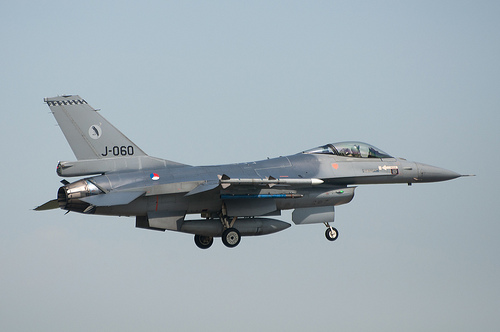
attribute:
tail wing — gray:
[43, 94, 146, 159]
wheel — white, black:
[222, 226, 240, 247]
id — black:
[100, 143, 135, 158]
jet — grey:
[34, 82, 474, 246]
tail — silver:
[40, 161, 105, 220]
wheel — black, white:
[221, 226, 241, 247]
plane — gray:
[26, 92, 478, 252]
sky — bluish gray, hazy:
[2, 2, 498, 329]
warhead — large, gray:
[173, 211, 293, 240]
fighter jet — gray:
[36, 91, 479, 249]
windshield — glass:
[310, 141, 392, 160]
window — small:
[307, 141, 391, 160]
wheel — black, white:
[327, 227, 341, 239]